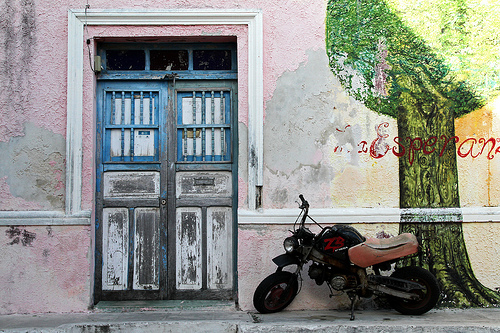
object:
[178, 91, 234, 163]
blue rails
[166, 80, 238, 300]
door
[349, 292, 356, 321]
kick stand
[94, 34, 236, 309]
doors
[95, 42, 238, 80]
window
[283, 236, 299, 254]
headlight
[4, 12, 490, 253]
building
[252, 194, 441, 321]
motorcycle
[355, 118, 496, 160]
word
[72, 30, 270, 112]
windows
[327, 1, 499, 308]
tree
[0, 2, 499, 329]
building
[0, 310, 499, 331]
concrete sidewalk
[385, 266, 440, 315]
wheel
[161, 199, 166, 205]
lock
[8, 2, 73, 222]
wall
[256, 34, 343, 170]
wall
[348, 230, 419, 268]
seat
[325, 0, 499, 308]
mural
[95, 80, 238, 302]
door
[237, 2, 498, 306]
wall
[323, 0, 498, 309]
green tree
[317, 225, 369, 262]
logo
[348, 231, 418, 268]
motorcycle tank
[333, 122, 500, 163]
language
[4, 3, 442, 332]
building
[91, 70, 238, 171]
rails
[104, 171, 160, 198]
mail slot